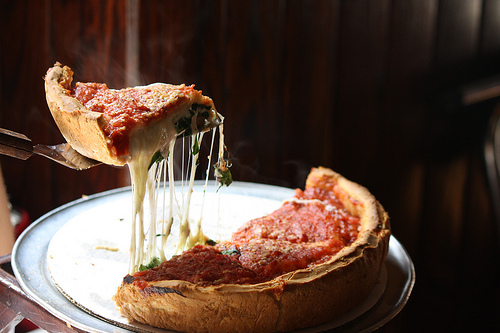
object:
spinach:
[174, 108, 234, 188]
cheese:
[127, 125, 217, 222]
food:
[40, 51, 263, 206]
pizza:
[115, 165, 394, 326]